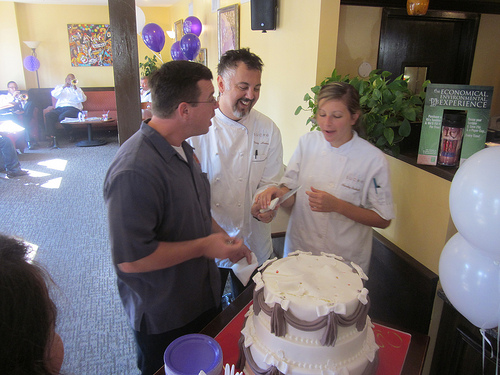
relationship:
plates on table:
[163, 332, 224, 373] [151, 282, 431, 373]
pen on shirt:
[368, 167, 378, 189] [274, 124, 399, 283]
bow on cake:
[250, 272, 267, 294] [237, 241, 379, 367]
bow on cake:
[264, 288, 295, 313] [237, 241, 379, 367]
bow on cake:
[315, 295, 350, 319] [237, 241, 379, 367]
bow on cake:
[352, 287, 371, 307] [237, 241, 379, 367]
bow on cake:
[351, 257, 368, 281] [237, 241, 379, 367]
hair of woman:
[315, 79, 357, 117] [282, 82, 393, 275]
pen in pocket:
[252, 147, 261, 162] [248, 153, 270, 173]